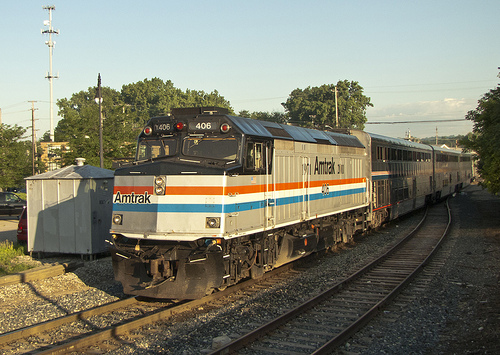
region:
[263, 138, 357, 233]
silver paint on train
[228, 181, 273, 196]
orange paint on train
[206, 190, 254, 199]
white paint on train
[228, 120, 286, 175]
black paint on train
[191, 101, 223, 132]
white numbers on train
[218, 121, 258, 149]
red light on train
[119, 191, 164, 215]
black letters on train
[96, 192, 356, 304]
silver train on track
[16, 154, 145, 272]
silver shed by train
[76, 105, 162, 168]
green tree by train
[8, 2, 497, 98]
The sky is clear blue.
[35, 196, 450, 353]
The tracks are clear.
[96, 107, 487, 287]
The train is silver.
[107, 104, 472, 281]
The train is on the tracks.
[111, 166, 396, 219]
The stripes are orange, white and blue.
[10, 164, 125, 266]
The structure is gray.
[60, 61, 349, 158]
The trees are leafy.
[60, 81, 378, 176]
The trees are green.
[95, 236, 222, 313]
The grill is black.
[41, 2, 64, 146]
The lights are off.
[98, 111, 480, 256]
silver train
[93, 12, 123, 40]
white clouds in blue sky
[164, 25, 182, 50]
white clouds in blue sky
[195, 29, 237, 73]
white clouds in blue sky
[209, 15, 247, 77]
white clouds in blue sky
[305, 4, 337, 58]
white clouds in blue sky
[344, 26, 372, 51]
white clouds in blue sky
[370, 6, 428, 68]
white clouds in blue sky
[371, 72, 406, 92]
white clouds in blue sky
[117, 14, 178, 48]
white clouds in blue sky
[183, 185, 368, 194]
an orange stripe on a train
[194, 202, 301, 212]
a blue stripe on train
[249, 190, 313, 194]
a white stripe on a train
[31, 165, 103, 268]
a small silver building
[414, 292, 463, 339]
gray gravel scattered on the ground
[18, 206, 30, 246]
the back end of a vehicle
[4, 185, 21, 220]
a black truck parked nearby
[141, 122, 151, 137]
a round red light on the train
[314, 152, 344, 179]
a black logo on the train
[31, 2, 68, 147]
a tall metal cell phone tower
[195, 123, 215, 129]
The number 406 on the right.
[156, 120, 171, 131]
The number 406 on the left.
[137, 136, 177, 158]
The left window on the front of the train.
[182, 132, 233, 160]
The right side window on the front of the train.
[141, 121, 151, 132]
The red light on the left.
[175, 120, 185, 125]
The red light in the middle.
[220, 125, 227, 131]
The red light on the right.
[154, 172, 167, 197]
The two lights in the middle on the front.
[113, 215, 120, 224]
The left headlight of the train.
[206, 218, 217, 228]
The right headlight on the train.